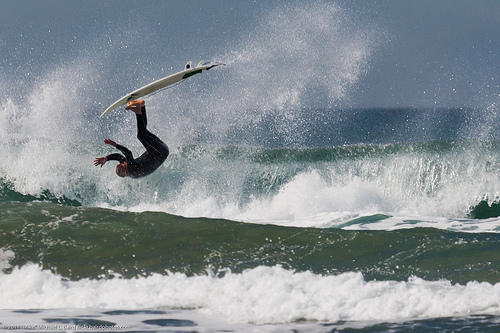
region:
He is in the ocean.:
[14, 19, 492, 315]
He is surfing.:
[80, 62, 221, 244]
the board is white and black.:
[77, 22, 207, 143]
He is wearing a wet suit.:
[72, 87, 175, 195]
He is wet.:
[86, 83, 183, 250]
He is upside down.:
[90, 76, 216, 251]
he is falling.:
[79, 34, 231, 269]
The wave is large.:
[48, 78, 460, 265]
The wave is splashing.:
[25, 39, 492, 289]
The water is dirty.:
[14, 19, 482, 319]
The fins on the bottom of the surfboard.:
[180, 57, 206, 67]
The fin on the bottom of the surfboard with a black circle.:
[187, 58, 193, 68]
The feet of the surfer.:
[122, 102, 147, 113]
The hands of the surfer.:
[85, 140, 114, 165]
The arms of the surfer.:
[106, 137, 131, 164]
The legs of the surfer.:
[130, 107, 160, 144]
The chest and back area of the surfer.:
[126, 152, 166, 181]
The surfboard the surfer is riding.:
[83, 60, 227, 116]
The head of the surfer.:
[113, 162, 134, 176]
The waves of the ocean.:
[7, 79, 494, 331]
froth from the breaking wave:
[22, 251, 195, 331]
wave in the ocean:
[33, 205, 335, 278]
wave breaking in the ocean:
[166, 121, 480, 238]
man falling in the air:
[94, 92, 163, 203]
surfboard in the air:
[86, 58, 237, 117]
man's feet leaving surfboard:
[115, 85, 150, 120]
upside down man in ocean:
[88, 89, 157, 231]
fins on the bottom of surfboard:
[166, 56, 216, 76]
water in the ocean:
[34, 230, 218, 265]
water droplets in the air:
[245, 63, 382, 103]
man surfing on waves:
[27, 10, 475, 332]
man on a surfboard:
[61, 40, 247, 265]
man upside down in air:
[48, 36, 200, 246]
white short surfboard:
[83, 40, 241, 127]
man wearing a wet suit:
[72, 44, 237, 217]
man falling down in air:
[81, 23, 256, 218]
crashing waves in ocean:
[93, 225, 440, 323]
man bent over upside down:
[78, 100, 155, 237]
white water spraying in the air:
[66, 14, 345, 202]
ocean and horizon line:
[130, 53, 437, 263]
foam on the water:
[34, 313, 209, 331]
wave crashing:
[286, 171, 441, 227]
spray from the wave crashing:
[245, 92, 497, 202]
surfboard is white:
[107, 58, 256, 129]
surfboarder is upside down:
[103, 117, 193, 201]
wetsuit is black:
[113, 107, 190, 202]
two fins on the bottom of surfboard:
[185, 50, 237, 81]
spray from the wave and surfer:
[63, 9, 257, 214]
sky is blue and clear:
[286, 15, 498, 98]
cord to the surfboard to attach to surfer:
[133, 67, 203, 109]